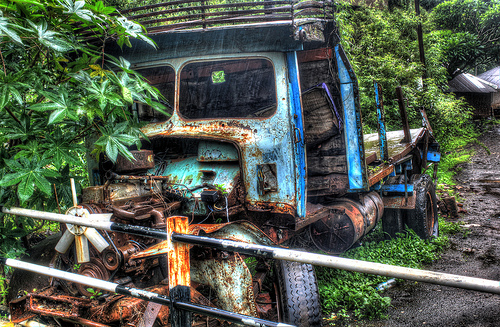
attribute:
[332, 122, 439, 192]
truck bed — blue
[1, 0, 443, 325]
truck — blue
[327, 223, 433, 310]
weeds — green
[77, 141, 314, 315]
truck — wrecked, rusty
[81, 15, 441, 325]
truck — old, broken, blue, rusty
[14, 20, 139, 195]
tree — green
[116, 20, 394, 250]
truck — blue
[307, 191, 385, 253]
barrel — under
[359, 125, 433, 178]
truck bed — broken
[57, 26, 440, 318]
truck — blue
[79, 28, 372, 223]
truck cab — blue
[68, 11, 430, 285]
truck — blue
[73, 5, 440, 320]
rusty truck — old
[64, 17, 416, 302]
truck — old, rusty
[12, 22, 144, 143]
leaves — wet, green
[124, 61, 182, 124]
windshield — rusty, old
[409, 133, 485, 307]
path — end 